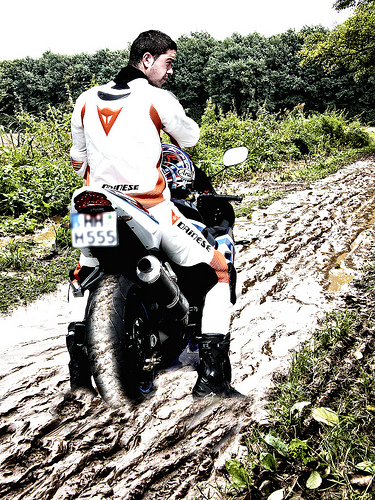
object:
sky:
[0, 0, 356, 58]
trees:
[286, 1, 375, 129]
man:
[49, 26, 229, 252]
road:
[0, 153, 374, 495]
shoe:
[190, 331, 250, 401]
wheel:
[86, 268, 166, 410]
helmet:
[157, 142, 199, 202]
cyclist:
[68, 30, 249, 405]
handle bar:
[169, 133, 204, 147]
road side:
[223, 237, 374, 496]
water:
[324, 266, 354, 298]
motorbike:
[64, 144, 249, 411]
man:
[55, 21, 209, 181]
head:
[129, 30, 179, 87]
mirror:
[220, 145, 249, 170]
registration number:
[68, 206, 117, 249]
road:
[240, 172, 367, 345]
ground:
[0, 385, 69, 494]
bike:
[66, 144, 249, 418]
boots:
[188, 333, 245, 402]